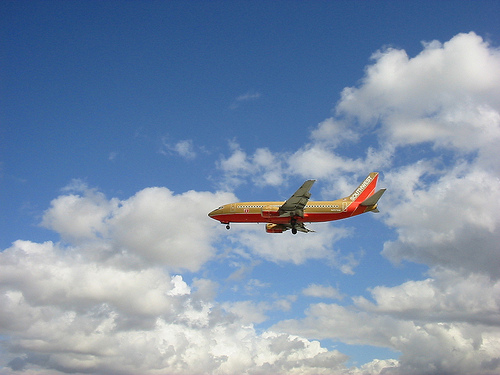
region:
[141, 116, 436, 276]
a plane in the sky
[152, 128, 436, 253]
the plane is gold and red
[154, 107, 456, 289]
a southwest airlines flight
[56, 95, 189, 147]
the sky is blue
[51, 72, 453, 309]
the sky is cloudy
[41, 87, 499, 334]
the clouds are fluffy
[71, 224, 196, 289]
the clouds are white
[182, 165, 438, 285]
this is a passenger jet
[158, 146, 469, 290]
the wheels are down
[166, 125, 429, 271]
the font is white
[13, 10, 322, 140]
bright blue sky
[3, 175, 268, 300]
puffy white sky clouds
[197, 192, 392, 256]
plane flying through clouds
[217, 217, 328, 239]
landing gear of plane deployed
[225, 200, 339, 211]
windows of flying plane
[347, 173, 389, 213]
back wings in the air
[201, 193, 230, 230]
nose of the plane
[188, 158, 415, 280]
plane in front of the couds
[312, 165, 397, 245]
red stripe on tailof plane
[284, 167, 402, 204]
name of airplane on tailfin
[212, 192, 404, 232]
this is a jet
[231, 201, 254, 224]
the jet is red and yellow in color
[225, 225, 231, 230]
this is the front wheel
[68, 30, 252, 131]
this is the sky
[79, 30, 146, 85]
the sky is blue in color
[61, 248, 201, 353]
these are the clouds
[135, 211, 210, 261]
the cloud is whiter in color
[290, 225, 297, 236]
this is the hind wheel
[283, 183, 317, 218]
this is the wing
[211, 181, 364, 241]
the jet is on air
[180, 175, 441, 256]
a plane flying in the sky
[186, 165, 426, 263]
a yellow and red plane in the sky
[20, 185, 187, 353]
fluffy white clouds in the sky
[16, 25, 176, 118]
a patch of blue sky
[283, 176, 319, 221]
a plane's wing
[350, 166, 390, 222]
the red and yellow tail of a plane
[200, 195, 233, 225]
a plane's cockpit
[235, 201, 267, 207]
a row of window on a plane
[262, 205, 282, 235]
two plane propellers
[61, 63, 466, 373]
a plane in the sky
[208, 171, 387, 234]
A plane flying in the sky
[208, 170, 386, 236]
A red and beige airplane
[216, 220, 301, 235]
The wheels on the bottom of the plane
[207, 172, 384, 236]
A passenger plane preparing to land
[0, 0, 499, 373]
A clear blue sky with fluffy white clouds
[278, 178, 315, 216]
A plane wing with a silvery underside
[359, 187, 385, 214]
The plane's tail fins with white undersides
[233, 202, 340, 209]
Passenger windows on the plane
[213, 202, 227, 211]
The cockpit windows on the plane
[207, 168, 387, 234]
A Southwest plane descending